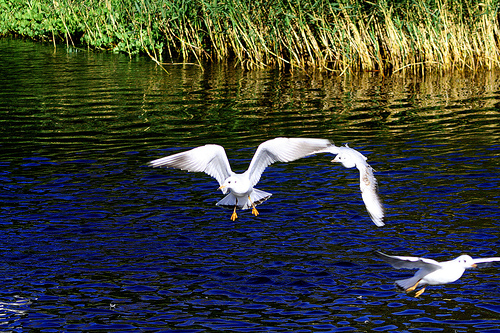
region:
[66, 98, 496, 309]
white birds over the water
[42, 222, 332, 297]
the water is extremely blue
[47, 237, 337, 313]
this water has a deep blue color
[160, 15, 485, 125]
this part of the water is reflecting the grass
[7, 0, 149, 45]
wild green grass on the shore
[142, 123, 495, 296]
three white doves flying over the water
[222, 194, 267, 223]
the bird has orange legs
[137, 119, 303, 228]
this bird resembles a dove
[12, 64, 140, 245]
the water has two colors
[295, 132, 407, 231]
this bird is flying sideways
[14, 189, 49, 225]
dark spot in water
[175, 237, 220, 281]
dark spot in water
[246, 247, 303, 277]
dark spot in water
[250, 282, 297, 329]
dark spot in water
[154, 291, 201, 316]
dark spot in water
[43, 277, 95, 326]
dark spot in water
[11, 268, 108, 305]
Small ripples in the water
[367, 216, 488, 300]
White bird above the water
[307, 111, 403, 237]
White bird in the water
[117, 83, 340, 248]
White bird above the water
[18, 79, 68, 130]
Small ripples in the water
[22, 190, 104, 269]
Small ripples in the water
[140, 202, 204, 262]
Small ripples in the water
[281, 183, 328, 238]
Small ripples in the water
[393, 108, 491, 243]
Small ripples in the water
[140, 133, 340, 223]
A bird flies over the water.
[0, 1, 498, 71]
Some plants grow in the water.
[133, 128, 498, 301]
A group of birds fly over the water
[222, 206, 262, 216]
The bird has yellow feet.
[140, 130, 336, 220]
The bird flying over the water is white.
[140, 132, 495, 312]
These birds are bright white.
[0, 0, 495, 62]
The plants in the water are green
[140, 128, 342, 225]
The bird's wings are outspread.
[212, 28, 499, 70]
The stalks of the plants are brown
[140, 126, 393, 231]
two birds flying together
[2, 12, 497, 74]
grass next to the water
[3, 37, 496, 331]
a body of water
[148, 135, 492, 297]
white birds in the water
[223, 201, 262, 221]
the orange feet on the bird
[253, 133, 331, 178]
the wing on the bird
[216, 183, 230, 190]
the beak on the bird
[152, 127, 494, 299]
birds flying over the water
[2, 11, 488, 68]
weeds in the water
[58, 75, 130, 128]
Large body of water